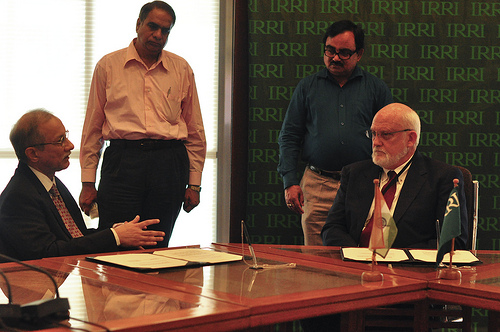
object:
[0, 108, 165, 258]
man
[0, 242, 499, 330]
table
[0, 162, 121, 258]
suit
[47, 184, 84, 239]
tie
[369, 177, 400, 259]
flag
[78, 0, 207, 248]
man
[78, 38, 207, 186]
shirt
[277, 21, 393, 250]
man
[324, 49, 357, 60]
glasses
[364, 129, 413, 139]
glasses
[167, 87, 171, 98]
pen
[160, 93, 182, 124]
pocket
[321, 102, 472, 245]
man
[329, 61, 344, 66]
mustache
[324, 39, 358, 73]
face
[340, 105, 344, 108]
button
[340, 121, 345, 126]
button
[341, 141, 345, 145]
button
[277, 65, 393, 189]
shirt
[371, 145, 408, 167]
beard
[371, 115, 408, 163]
face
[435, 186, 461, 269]
flag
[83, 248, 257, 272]
booklet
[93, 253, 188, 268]
papers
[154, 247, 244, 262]
papers